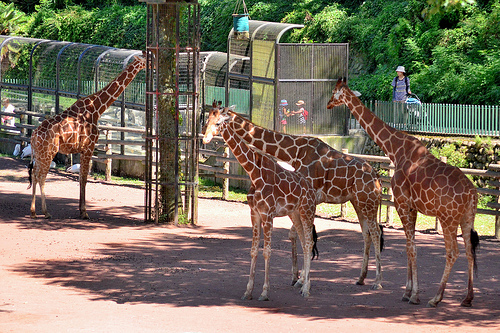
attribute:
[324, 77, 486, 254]
giraffe — fenced